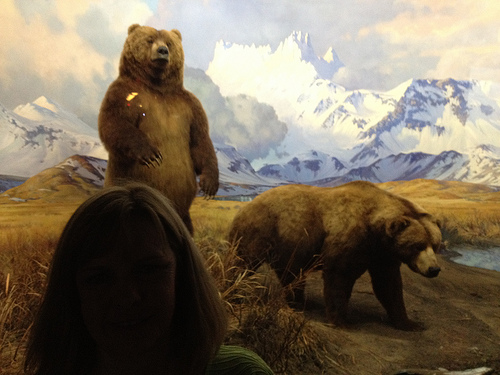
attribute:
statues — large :
[224, 174, 463, 348]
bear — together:
[93, 23, 218, 280]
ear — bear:
[127, 23, 139, 33]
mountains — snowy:
[9, 42, 481, 164]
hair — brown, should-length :
[60, 217, 192, 354]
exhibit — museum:
[1, 0, 499, 374]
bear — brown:
[81, 4, 262, 269]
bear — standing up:
[103, 13, 221, 247]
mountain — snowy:
[0, 6, 494, 184]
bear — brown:
[229, 180, 446, 329]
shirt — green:
[195, 335, 268, 372]